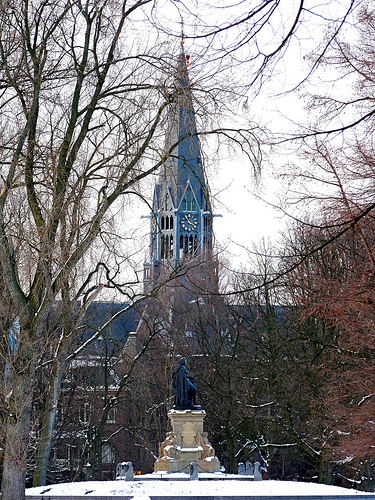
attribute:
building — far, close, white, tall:
[148, 19, 228, 348]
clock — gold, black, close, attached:
[163, 207, 212, 244]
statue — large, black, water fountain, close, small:
[162, 353, 221, 413]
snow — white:
[185, 475, 247, 500]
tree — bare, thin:
[40, 27, 180, 228]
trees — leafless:
[1, 0, 95, 483]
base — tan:
[149, 455, 222, 472]